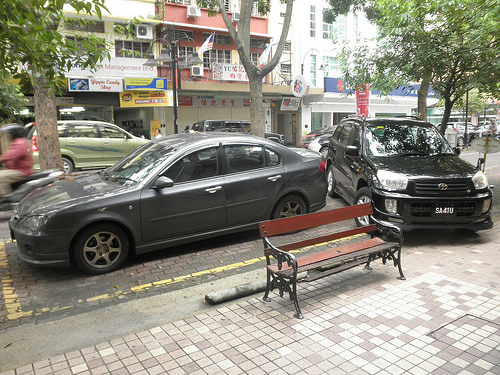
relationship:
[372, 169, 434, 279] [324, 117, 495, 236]
front licence plate on a black car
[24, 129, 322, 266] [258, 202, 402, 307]
car parked behind a bench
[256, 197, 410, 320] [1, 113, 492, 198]
bench beside road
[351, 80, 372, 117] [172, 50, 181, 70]
banner hanging from a building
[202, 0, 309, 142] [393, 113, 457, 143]
tree beside a car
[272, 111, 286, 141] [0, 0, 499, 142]
door in a building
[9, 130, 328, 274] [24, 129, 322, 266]
car parked in front of black car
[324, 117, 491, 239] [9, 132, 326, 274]
black car behind grey car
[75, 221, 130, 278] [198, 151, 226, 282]
tire of a car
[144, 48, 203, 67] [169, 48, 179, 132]
lights on post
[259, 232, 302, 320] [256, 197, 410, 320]
side on bench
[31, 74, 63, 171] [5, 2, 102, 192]
brown trunk on tree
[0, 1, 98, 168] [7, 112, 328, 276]
tree behind car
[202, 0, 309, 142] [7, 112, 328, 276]
tree behind car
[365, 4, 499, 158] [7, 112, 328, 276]
tree behind car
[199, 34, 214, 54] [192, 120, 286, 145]
flag above car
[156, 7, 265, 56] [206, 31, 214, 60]
frame next to flag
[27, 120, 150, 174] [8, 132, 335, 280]
car behind car